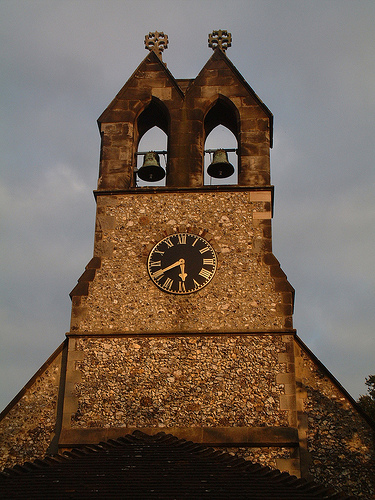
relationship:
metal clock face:
[186, 241, 210, 254] [148, 234, 215, 292]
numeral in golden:
[200, 257, 216, 269] [174, 258, 188, 280]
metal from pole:
[186, 241, 210, 254] [206, 142, 237, 154]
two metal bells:
[131, 138, 241, 185] [204, 146, 247, 181]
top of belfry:
[94, 26, 274, 187] [0, 30, 375, 499]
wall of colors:
[72, 333, 288, 433] [212, 196, 240, 221]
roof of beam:
[95, 22, 263, 101] [135, 147, 238, 156]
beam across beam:
[124, 142, 242, 162] [135, 147, 238, 156]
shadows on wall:
[288, 374, 369, 492] [72, 333, 288, 433]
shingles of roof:
[95, 181, 287, 197] [95, 22, 263, 101]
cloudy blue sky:
[27, 22, 76, 56] [234, 3, 373, 71]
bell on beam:
[138, 148, 167, 187] [135, 147, 238, 156]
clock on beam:
[138, 226, 224, 298] [135, 147, 238, 156]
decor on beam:
[130, 21, 174, 56] [135, 147, 238, 156]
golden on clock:
[178, 259, 187, 282] [138, 226, 224, 298]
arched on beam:
[197, 94, 243, 187] [135, 147, 238, 156]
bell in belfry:
[138, 148, 167, 187] [0, 30, 375, 499]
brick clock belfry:
[243, 110, 269, 180] [0, 30, 375, 499]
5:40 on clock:
[154, 258, 189, 286] [138, 226, 224, 298]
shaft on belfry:
[215, 166, 224, 178] [0, 30, 375, 499]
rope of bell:
[205, 147, 216, 186] [138, 148, 167, 187]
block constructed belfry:
[245, 135, 271, 175] [97, 41, 271, 187]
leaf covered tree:
[363, 374, 374, 386] [342, 367, 374, 422]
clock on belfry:
[138, 226, 224, 298] [0, 30, 375, 499]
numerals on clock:
[163, 236, 204, 248] [138, 226, 224, 298]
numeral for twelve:
[200, 257, 216, 269] [176, 232, 188, 247]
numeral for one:
[200, 257, 216, 269] [190, 235, 202, 248]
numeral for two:
[200, 257, 216, 269] [199, 243, 211, 255]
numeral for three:
[200, 257, 216, 269] [198, 255, 219, 268]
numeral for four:
[200, 257, 216, 269] [193, 266, 214, 281]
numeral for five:
[200, 257, 216, 269] [189, 274, 203, 294]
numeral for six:
[200, 257, 216, 269] [175, 277, 189, 295]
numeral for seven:
[200, 257, 216, 269] [159, 275, 175, 292]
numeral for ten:
[200, 257, 216, 269] [151, 246, 168, 256]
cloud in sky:
[230, 9, 279, 46] [234, 3, 373, 71]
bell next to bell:
[138, 148, 167, 187] [206, 149, 233, 179]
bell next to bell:
[138, 148, 167, 187] [135, 150, 167, 182]